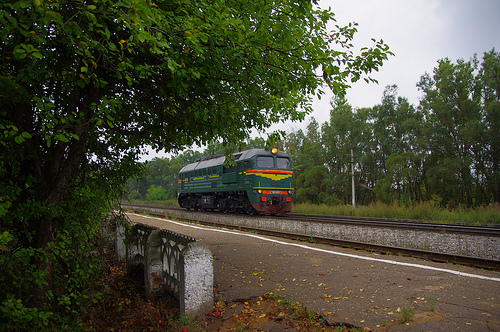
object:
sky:
[316, 0, 500, 66]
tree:
[416, 56, 484, 206]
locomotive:
[177, 148, 294, 216]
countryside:
[0, 22, 499, 331]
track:
[126, 208, 500, 269]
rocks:
[377, 234, 381, 237]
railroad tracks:
[122, 205, 499, 271]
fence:
[93, 205, 217, 320]